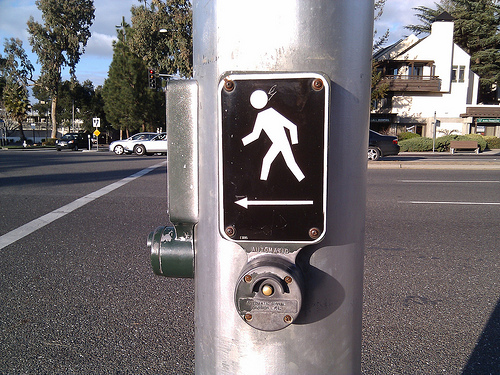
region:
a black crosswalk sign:
[217, 72, 330, 243]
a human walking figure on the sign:
[240, 87, 307, 184]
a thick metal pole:
[190, 0, 374, 371]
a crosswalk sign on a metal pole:
[191, 0, 376, 374]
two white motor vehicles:
[108, 130, 164, 155]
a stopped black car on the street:
[53, 129, 88, 154]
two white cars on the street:
[108, 130, 165, 156]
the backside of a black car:
[369, 130, 401, 159]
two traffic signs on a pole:
[90, 116, 100, 149]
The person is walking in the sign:
[192, 68, 351, 273]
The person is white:
[219, 70, 348, 232]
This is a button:
[247, 271, 289, 313]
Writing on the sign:
[252, 78, 297, 110]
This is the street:
[29, 251, 144, 355]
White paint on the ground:
[12, 121, 136, 296]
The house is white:
[374, 35, 486, 165]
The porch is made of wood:
[374, 54, 453, 99]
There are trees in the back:
[6, 7, 194, 151]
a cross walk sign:
[108, 22, 408, 359]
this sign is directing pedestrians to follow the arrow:
[205, 65, 340, 341]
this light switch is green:
[102, 210, 209, 274]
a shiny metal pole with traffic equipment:
[168, 12, 371, 373]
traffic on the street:
[39, 115, 161, 172]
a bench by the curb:
[436, 127, 494, 161]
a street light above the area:
[127, 15, 179, 87]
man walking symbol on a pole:
[232, 85, 314, 190]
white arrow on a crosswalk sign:
[228, 190, 326, 215]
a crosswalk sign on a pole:
[208, 54, 339, 262]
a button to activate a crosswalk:
[217, 247, 314, 341]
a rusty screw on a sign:
[308, 71, 327, 96]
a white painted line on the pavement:
[55, 177, 104, 236]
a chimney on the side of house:
[429, 5, 458, 101]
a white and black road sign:
[85, 110, 105, 130]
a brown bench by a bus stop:
[445, 134, 485, 158]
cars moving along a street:
[103, 122, 164, 161]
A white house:
[378, 9, 498, 136]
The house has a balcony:
[380, 53, 447, 96]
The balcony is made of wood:
[384, 50, 446, 95]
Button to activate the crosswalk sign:
[235, 262, 300, 327]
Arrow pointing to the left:
[226, 185, 329, 218]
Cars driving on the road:
[55, 113, 182, 163]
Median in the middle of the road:
[376, 149, 495, 175]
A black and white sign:
[192, 53, 372, 255]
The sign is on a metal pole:
[187, 22, 378, 369]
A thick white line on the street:
[17, 155, 149, 260]